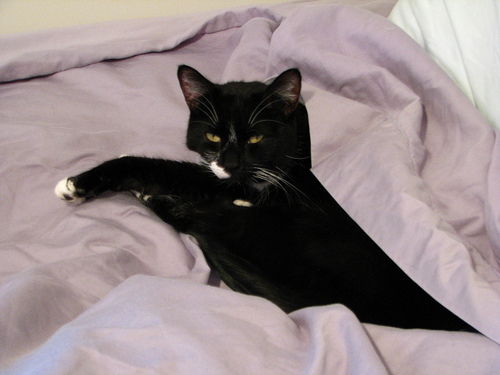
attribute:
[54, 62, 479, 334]
cat — black, short haired, tired, white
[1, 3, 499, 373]
blanket — purple, lavender, wrinkled, light purple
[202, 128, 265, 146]
eyes — green, yellow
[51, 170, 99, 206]
paw — white, black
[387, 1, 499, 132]
pillow — white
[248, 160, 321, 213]
whiskers — white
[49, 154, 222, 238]
legs — crossed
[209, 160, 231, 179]
spot — white